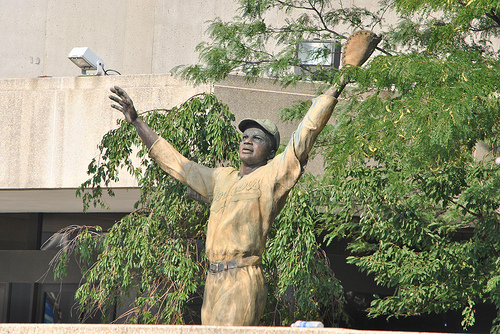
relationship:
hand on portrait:
[340, 68, 359, 83] [104, 26, 383, 326]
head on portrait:
[239, 118, 281, 166] [104, 26, 383, 326]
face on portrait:
[233, 125, 270, 163] [104, 26, 383, 326]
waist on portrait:
[195, 243, 255, 267] [104, 26, 383, 326]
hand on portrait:
[98, 83, 155, 146] [104, 26, 383, 326]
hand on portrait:
[109, 85, 155, 146] [104, 26, 383, 326]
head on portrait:
[234, 115, 271, 166] [104, 26, 383, 326]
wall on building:
[0, 74, 211, 190] [15, 78, 485, 319]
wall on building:
[0, 81, 180, 182] [2, 80, 437, 331]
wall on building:
[5, 0, 151, 180] [2, 80, 437, 331]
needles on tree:
[38, 211, 88, 274] [50, 117, 305, 323]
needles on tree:
[143, 184, 194, 264] [53, 120, 341, 326]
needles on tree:
[360, 245, 411, 315] [347, 65, 485, 322]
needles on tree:
[362, 175, 442, 253] [321, 7, 484, 327]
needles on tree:
[401, 97, 461, 178] [331, 49, 484, 320]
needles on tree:
[179, 0, 301, 84] [190, 4, 483, 314]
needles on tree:
[167, 95, 235, 154] [140, 91, 351, 331]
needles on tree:
[383, 3, 453, 51] [321, 7, 484, 327]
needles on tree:
[202, 19, 225, 36] [164, 5, 480, 301]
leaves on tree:
[76, 180, 88, 198] [53, 98, 341, 327]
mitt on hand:
[339, 28, 378, 77] [340, 68, 359, 83]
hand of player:
[340, 68, 359, 83] [101, 28, 396, 330]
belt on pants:
[204, 250, 259, 272] [198, 264, 264, 329]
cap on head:
[235, 118, 279, 153] [232, 117, 273, 167]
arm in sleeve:
[110, 83, 210, 203] [144, 135, 224, 211]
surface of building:
[3, 80, 403, 199] [7, 6, 482, 300]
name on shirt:
[211, 178, 265, 218] [147, 135, 302, 254]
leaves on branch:
[78, 238, 93, 264] [44, 225, 104, 254]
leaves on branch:
[103, 126, 129, 167] [117, 106, 176, 121]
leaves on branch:
[194, 99, 208, 111] [174, 92, 205, 119]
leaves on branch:
[134, 294, 154, 302] [154, 280, 170, 300]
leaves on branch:
[281, 254, 291, 274] [290, 215, 296, 251]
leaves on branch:
[304, 192, 324, 205] [301, 187, 348, 206]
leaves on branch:
[374, 215, 399, 246] [382, 234, 450, 289]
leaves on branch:
[337, 112, 350, 129] [321, 128, 406, 168]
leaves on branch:
[211, 66, 230, 79] [197, 48, 277, 81]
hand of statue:
[109, 85, 155, 146] [106, 68, 347, 330]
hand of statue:
[337, 53, 363, 82] [106, 68, 347, 330]